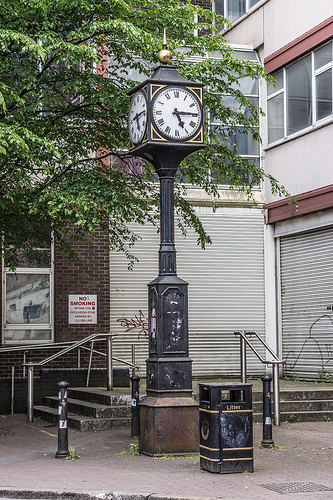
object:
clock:
[150, 83, 202, 144]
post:
[144, 145, 192, 398]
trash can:
[200, 381, 254, 475]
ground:
[0, 410, 332, 500]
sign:
[69, 296, 97, 324]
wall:
[0, 198, 273, 376]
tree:
[0, 0, 299, 272]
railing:
[233, 330, 287, 427]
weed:
[128, 439, 138, 457]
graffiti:
[117, 310, 148, 341]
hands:
[176, 111, 199, 129]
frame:
[258, 20, 331, 76]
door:
[272, 227, 333, 379]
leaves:
[21, 42, 50, 63]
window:
[2, 269, 52, 342]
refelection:
[7, 276, 49, 324]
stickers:
[151, 309, 157, 340]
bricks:
[79, 244, 102, 255]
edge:
[0, 488, 28, 499]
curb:
[2, 488, 142, 499]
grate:
[261, 479, 332, 496]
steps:
[252, 391, 333, 426]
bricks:
[87, 458, 133, 483]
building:
[1, 0, 332, 407]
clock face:
[153, 87, 201, 139]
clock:
[128, 90, 148, 145]